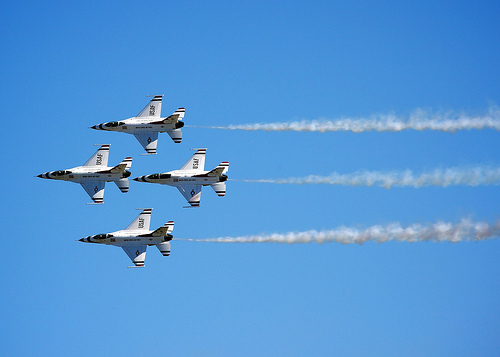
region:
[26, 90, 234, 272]
four jets in a group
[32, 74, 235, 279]
four jets in a pack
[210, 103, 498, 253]
vapor trails from jets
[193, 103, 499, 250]
three vapor trails from jets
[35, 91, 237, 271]
a group of planes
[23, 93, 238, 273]
a group of airplanes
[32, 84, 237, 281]
airplanes in the air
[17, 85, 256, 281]
airplanes in the sky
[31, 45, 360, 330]
blue sky beyond the planes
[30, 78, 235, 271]
four planes close together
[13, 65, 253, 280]
four planes flying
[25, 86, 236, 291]
four planes in the sky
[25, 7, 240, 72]
the sky is blue and clear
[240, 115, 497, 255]
three exhaust plumes behind the planes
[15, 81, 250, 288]
the planes are F16's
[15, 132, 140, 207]
the lead plane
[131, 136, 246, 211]
the trailing plane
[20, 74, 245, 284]
four planes in diamond formation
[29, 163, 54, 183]
the nose of the lead plane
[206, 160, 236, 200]
the tail of the trailing plane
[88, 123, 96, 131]
nose of a jet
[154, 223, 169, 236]
the rudder of a jet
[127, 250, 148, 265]
the elevator of a jet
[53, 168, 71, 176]
the cockpit of a jet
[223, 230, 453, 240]
smoke fume for the jet engine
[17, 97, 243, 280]
four jets flying in the sky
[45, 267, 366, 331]
blue skies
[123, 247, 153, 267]
the wing of a plane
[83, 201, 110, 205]
missile launcher of a jet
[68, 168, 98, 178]
fuselage of a jet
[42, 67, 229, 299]
four planes flying in the sky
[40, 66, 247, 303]
four planes flying in a pattern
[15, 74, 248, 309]
four planes flying very close to each other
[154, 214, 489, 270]
smoke coming from a plane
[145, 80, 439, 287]
three planes with smoke coming from them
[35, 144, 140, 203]
a white plane with stripes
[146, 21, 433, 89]
a clear blue sky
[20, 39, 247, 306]
four planes flying in a clear blue sky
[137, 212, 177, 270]
the tail wing on a plane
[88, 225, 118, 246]
the cock pit of a plane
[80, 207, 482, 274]
a plane blowing smoke out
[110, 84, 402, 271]
three planes blowing smoke out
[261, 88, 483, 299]
three lines of smoke in the sky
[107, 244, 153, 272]
the wing of a plane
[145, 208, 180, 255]
the tail wing of a plane